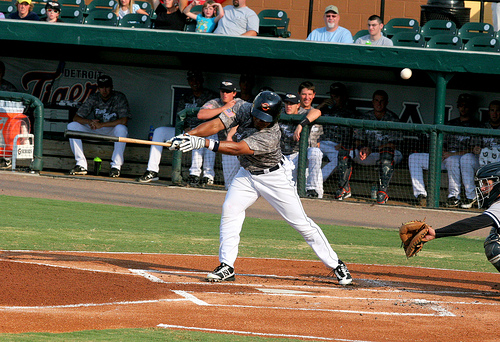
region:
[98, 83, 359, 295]
a baseball player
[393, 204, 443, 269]
a brown worn catchers mitt.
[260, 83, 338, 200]
a baseball player in a dugout.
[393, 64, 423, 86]
a flying white baseball.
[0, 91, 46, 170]
a red ice cooler.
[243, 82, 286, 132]
a black baseball helmet.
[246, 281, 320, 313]
a white base near a player.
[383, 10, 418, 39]
a seat in an audience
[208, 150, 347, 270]
a pair of white pants.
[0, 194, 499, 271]
a section of green grass.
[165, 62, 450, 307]
Man playing baseball on the field.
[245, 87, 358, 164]
Helmet on the ball player.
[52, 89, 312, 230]
Bat being held by the player.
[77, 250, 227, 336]
White lines on the field.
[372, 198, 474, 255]
Mitt on the catcher.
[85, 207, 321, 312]
Grass on the field.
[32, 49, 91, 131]
Detroit Tiger logo in the dugout.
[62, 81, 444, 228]
Men sitting in the dugout.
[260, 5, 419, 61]
chairs in the background.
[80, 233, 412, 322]
Shoes on the man.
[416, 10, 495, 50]
empty green stadium seats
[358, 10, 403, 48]
man in a gray shirt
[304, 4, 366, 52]
man with a beard wearing a hat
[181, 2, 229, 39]
girl with her arms up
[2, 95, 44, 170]
orange beverage dispenser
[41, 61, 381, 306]
baseball player swinging his bat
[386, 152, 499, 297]
catcher holding out his glove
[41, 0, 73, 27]
boy wearing a hat and sunglasses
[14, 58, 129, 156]
Detroit Tigers logo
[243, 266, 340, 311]
home plate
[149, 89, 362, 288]
Man hitting baseball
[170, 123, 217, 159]
Both hands holding bat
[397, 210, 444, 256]
Catcher's brown glove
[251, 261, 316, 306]
Home plate is triangular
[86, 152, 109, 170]
Small green object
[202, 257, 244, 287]
Right foot of batter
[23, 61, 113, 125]
Tiger logo in background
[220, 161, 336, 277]
White pants on player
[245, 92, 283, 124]
Wearing black helmet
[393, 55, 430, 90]
Ball above heads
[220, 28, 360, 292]
a man in white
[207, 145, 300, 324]
a man in white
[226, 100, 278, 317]
a man in white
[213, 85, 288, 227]
a man in white